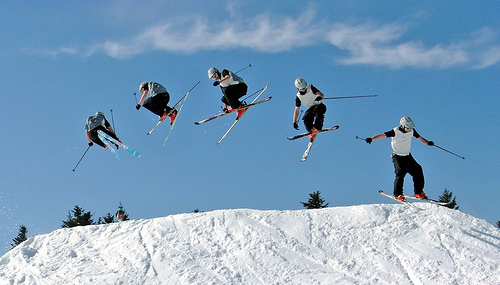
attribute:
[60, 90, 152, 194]
man — skiing, jumping, caucasion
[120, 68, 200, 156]
man — skiing, jumping, caucasion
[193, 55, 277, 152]
man — skiing, jumping, caucasion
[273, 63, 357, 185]
man — skiing, jumping, caucasion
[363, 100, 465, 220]
man — skiing, jumping, caucasion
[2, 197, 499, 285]
snow — white, cold, soft, ramp, surface